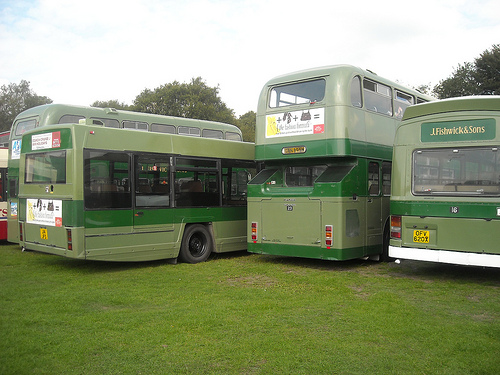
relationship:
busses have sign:
[244, 63, 437, 269] [261, 107, 330, 139]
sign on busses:
[261, 107, 330, 139] [244, 63, 437, 269]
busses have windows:
[244, 63, 437, 269] [363, 73, 395, 120]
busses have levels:
[244, 63, 437, 269] [249, 61, 438, 163]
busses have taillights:
[244, 63, 437, 269] [324, 222, 332, 250]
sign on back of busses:
[261, 107, 330, 139] [244, 63, 437, 269]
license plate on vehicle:
[410, 227, 430, 246] [387, 94, 498, 272]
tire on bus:
[178, 222, 213, 265] [14, 124, 262, 264]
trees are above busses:
[427, 41, 499, 101] [244, 63, 437, 269]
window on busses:
[267, 78, 328, 112] [244, 63, 437, 269]